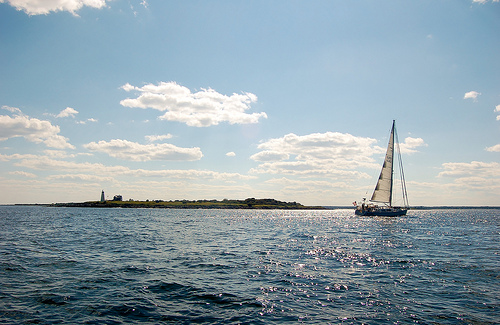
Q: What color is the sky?
A: Pale blue.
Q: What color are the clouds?
A: White.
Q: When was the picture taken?
A: Summer.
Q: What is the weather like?
A: Sunny with clouds.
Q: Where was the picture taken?
A: The lake.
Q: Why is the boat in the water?
A: To get to the island.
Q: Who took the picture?
A: A friend.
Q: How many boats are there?
A: One.